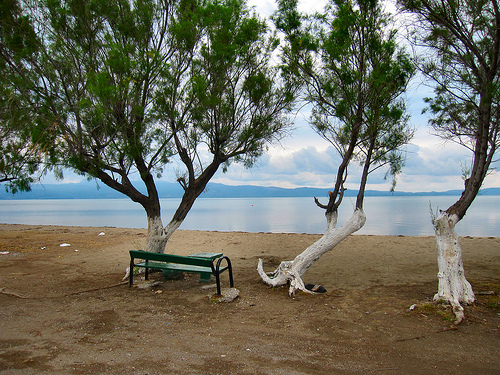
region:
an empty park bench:
[79, 226, 248, 301]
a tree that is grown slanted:
[258, 174, 384, 309]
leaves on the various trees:
[17, 21, 414, 211]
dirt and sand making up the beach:
[59, 289, 201, 374]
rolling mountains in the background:
[107, 181, 299, 204]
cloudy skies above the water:
[287, 124, 429, 189]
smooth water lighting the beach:
[238, 193, 443, 245]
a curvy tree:
[391, 63, 498, 333]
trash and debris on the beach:
[0, 208, 127, 278]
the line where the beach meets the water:
[56, 213, 376, 260]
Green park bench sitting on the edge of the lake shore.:
[122, 240, 238, 310]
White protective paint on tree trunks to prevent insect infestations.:
[251, 202, 488, 329]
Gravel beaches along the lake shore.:
[0, 223, 126, 331]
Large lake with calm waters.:
[198, 200, 320, 232]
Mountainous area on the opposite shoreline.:
[20, 173, 291, 199]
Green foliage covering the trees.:
[1, 0, 310, 177]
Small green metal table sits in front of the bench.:
[182, 247, 225, 282]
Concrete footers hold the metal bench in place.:
[203, 283, 248, 308]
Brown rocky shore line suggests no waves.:
[228, 229, 497, 265]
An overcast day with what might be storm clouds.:
[246, 107, 495, 187]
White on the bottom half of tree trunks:
[236, 172, 498, 348]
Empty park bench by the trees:
[73, 211, 424, 330]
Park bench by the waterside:
[2, 74, 499, 304]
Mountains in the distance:
[1, 118, 477, 249]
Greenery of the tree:
[3, 2, 455, 231]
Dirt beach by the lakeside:
[11, 187, 498, 362]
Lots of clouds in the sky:
[5, 78, 493, 244]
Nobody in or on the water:
[1, 145, 487, 255]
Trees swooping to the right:
[254, 1, 496, 357]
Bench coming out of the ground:
[117, 263, 286, 322]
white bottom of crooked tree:
[247, 191, 369, 309]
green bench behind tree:
[109, 231, 259, 309]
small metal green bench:
[118, 244, 244, 302]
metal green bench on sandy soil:
[110, 238, 250, 333]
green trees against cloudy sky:
[15, 25, 491, 197]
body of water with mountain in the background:
[219, 175, 299, 223]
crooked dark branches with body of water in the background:
[66, 158, 237, 220]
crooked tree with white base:
[417, 10, 495, 326]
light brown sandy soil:
[35, 314, 309, 366]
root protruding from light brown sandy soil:
[6, 239, 123, 310]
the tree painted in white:
[415, 183, 484, 338]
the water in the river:
[245, 198, 280, 232]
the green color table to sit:
[122, 240, 242, 305]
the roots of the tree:
[250, 243, 323, 328]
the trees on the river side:
[34, 61, 254, 177]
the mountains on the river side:
[220, 182, 295, 208]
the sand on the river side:
[31, 313, 191, 363]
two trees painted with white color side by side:
[251, 78, 479, 341]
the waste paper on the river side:
[55, 233, 82, 267]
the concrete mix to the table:
[209, 286, 252, 315]